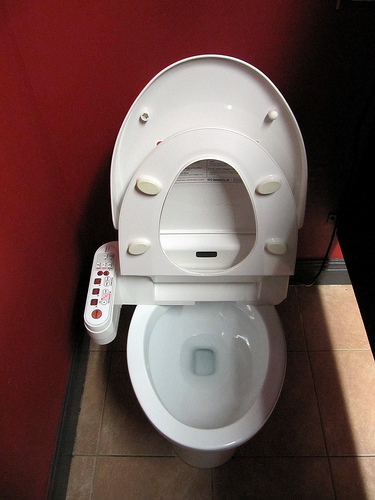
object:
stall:
[1, 8, 366, 490]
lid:
[107, 57, 309, 275]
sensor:
[193, 250, 217, 258]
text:
[177, 160, 239, 183]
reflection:
[230, 331, 254, 348]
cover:
[109, 53, 308, 282]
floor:
[282, 283, 372, 497]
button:
[88, 296, 98, 308]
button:
[92, 276, 99, 286]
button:
[96, 270, 104, 276]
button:
[100, 298, 108, 306]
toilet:
[126, 303, 287, 469]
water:
[185, 346, 217, 374]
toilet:
[83, 53, 310, 470]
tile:
[90, 456, 212, 498]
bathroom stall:
[19, 16, 355, 472]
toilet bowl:
[126, 307, 286, 464]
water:
[179, 336, 233, 383]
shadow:
[80, 146, 371, 499]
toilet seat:
[118, 125, 297, 278]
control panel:
[83, 242, 117, 328]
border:
[47, 336, 89, 500]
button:
[91, 309, 103, 319]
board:
[336, 2, 374, 362]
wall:
[3, 6, 341, 498]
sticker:
[174, 160, 245, 184]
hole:
[190, 347, 218, 377]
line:
[95, 453, 329, 462]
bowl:
[157, 312, 260, 417]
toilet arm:
[84, 240, 119, 345]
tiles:
[241, 431, 374, 497]